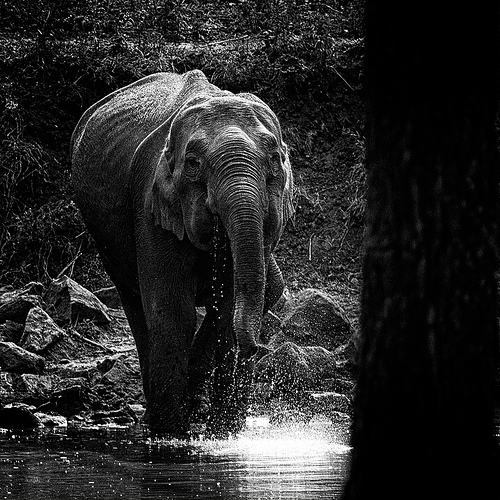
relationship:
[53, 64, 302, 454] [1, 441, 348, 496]
elephant walking in water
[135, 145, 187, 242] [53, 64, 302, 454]
ear of an elephant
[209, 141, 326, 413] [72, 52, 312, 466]
trunk of an elephant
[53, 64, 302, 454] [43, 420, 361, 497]
elephant on water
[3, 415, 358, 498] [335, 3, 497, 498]
river in forest